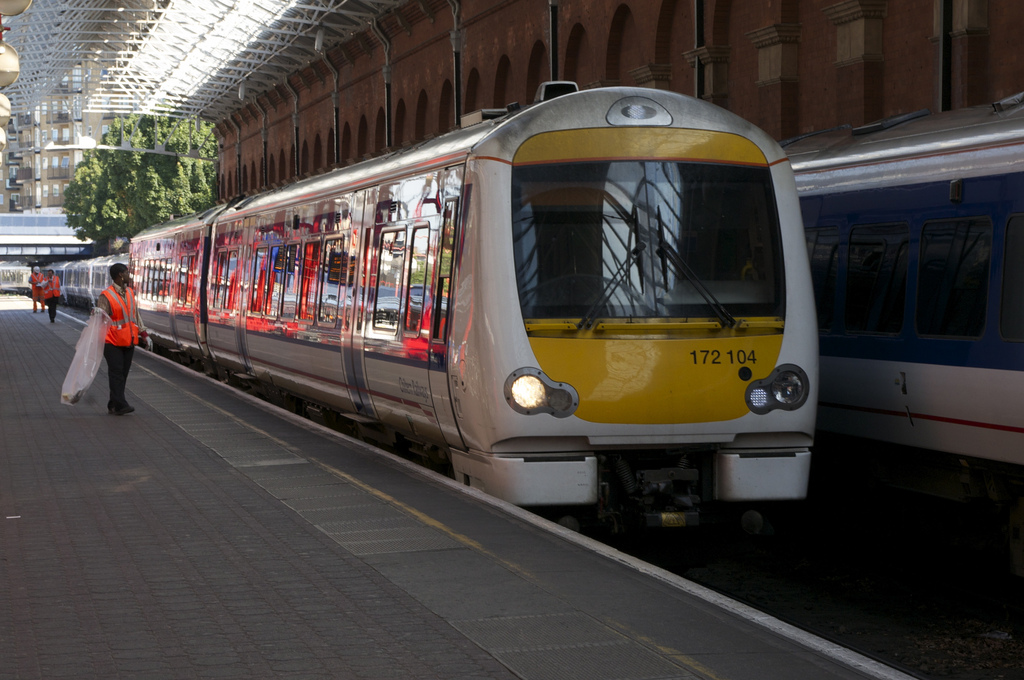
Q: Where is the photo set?
A: At a train station.